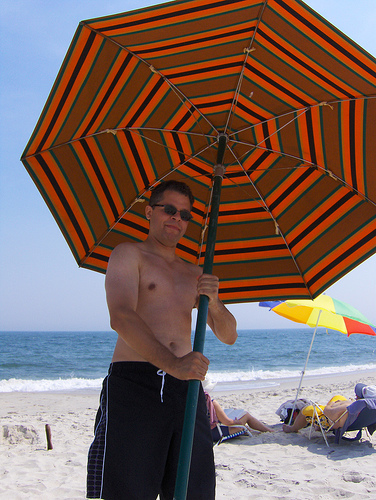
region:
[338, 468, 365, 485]
a foot step in sand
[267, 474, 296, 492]
a foot step in sand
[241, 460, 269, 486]
a foot step in sand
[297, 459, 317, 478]
a foot step in sand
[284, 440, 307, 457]
a foot step in sand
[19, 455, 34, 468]
a foot step in sand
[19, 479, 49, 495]
a foot step in sand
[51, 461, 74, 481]
a foot step in sand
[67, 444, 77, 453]
a foot step in sand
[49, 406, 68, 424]
a foot step in sand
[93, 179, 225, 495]
a man standing on the beach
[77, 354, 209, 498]
the black swim trunks the man is wearing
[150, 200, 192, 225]
the sunglasses on the man's face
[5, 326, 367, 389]
the ocean behind the man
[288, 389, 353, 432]
a man sitting in a chair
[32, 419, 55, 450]
a handle sticking out of the sand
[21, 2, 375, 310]
a big colorful striped umbrella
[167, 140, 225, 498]
the pole for the striped umbrella being held by the man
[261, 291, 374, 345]
a colorful umbrella above the sleeping man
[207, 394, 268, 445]
another person laying in a chair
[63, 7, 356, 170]
An orange, blue, and black striped umbrella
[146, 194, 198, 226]
Sunglasses on a man's face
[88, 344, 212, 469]
Black swim trunks worn by a man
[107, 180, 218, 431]
A man holding an umbrella pole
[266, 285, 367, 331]
A multi-colored umbrella propped in the sand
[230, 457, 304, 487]
Footprints in the sand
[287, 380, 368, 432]
A man reclining in a chair at the beach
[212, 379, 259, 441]
A woman reading at the beach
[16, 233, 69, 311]
A grey blue sky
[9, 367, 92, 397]
Waves coming to shore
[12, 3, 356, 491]
a beach scene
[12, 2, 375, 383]
a red and black umbrella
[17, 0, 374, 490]
a man holding an umbrella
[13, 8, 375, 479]
a man holds a striped umbrella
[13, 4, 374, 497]
a man holds a striped umbrella at the beach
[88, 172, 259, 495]
the man is wearing sunglasses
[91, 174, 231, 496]
the man is wearing a black bathing suit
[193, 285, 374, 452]
people sit under an umbrella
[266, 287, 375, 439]
a colorful umbrella stuck in the sand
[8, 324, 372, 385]
the ocean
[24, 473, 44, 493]
afoot step in the sand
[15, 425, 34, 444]
afoot step in the sand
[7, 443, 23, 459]
afoot step in the sand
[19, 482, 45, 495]
afoot step in the sand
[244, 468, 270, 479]
afoot step in the sand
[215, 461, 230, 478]
afoot step in the sand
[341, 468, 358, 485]
afoot step in the sand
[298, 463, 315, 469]
afoot step in the sand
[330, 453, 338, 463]
afoot step in the sand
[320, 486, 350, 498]
afoot step in the sand